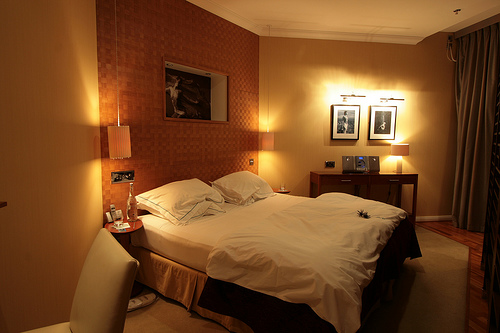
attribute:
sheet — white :
[131, 169, 408, 331]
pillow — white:
[220, 158, 262, 205]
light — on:
[383, 116, 423, 187]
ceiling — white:
[199, 0, 496, 51]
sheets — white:
[190, 147, 427, 325]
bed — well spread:
[130, 170, 423, 332]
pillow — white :
[137, 162, 229, 231]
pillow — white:
[130, 175, 226, 226]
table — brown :
[103, 214, 157, 315]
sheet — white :
[136, 170, 398, 307]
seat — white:
[39, 225, 224, 303]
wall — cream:
[2, 0, 104, 326]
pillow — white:
[134, 175, 224, 223]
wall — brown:
[1, 0, 260, 330]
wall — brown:
[258, 33, 451, 221]